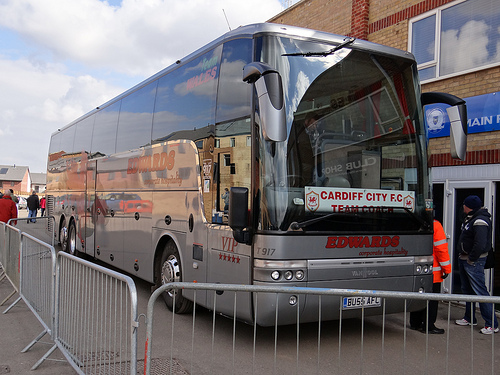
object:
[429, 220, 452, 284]
coat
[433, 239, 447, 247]
stripe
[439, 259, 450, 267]
stripe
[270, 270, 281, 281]
headlights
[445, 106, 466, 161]
mirror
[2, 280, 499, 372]
rail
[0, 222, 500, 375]
ground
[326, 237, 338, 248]
company letters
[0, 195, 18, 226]
red coat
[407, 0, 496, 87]
windows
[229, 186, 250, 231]
mirror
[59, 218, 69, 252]
tire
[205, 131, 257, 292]
door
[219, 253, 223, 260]
star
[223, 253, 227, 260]
star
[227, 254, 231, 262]
star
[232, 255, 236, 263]
star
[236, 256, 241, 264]
star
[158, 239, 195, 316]
tire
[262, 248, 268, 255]
identification number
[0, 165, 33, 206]
houses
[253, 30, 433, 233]
windshield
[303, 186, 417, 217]
sign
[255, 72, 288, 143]
mirror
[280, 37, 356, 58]
wiper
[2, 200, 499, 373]
street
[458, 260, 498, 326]
jeans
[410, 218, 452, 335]
man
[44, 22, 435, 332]
bus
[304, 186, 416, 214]
advertisement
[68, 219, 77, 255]
tire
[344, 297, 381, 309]
license plate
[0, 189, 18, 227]
people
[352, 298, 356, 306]
letter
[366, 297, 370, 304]
letter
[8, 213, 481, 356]
road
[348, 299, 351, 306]
number